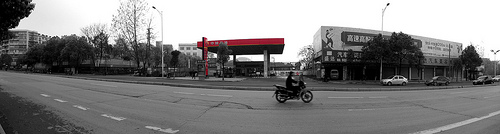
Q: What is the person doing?
A: Riding a motorcycle.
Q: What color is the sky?
A: White.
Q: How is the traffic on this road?
A: The traffic is light.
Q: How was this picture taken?
A: With a wide angle lens.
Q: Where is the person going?
A: To the right.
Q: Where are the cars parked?
A: By the side of the road.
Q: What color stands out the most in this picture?
A: Red.